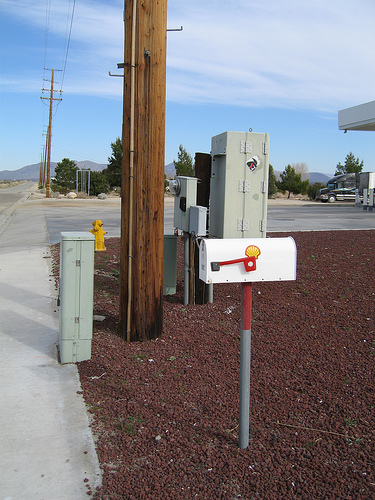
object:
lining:
[124, 0, 137, 342]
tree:
[275, 164, 309, 200]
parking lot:
[47, 195, 375, 245]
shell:
[245, 244, 261, 260]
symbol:
[245, 244, 261, 259]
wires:
[40, 0, 78, 157]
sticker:
[245, 155, 261, 173]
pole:
[119, 0, 167, 343]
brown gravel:
[42, 230, 374, 499]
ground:
[233, 118, 252, 145]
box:
[58, 231, 95, 365]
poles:
[39, 66, 65, 198]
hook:
[166, 25, 183, 32]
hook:
[108, 71, 124, 77]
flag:
[211, 252, 258, 273]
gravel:
[113, 223, 372, 324]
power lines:
[35, 0, 76, 173]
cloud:
[0, 0, 375, 177]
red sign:
[210, 246, 260, 272]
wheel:
[328, 194, 336, 202]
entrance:
[5, 199, 48, 254]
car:
[318, 171, 375, 204]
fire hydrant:
[89, 220, 106, 252]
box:
[199, 236, 297, 285]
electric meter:
[169, 176, 208, 237]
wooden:
[122, 203, 162, 343]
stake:
[199, 234, 297, 448]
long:
[119, 126, 137, 342]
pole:
[238, 282, 253, 451]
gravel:
[0, 306, 160, 500]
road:
[28, 338, 83, 498]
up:
[334, 257, 351, 299]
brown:
[124, 249, 138, 312]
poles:
[45, 0, 78, 94]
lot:
[303, 149, 352, 217]